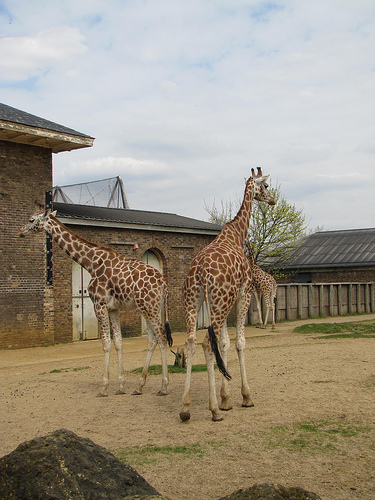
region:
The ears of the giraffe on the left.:
[46, 211, 57, 215]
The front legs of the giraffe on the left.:
[95, 311, 123, 395]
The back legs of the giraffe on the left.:
[132, 301, 169, 394]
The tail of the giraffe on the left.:
[161, 284, 172, 347]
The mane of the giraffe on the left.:
[48, 216, 124, 258]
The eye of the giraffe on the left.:
[27, 218, 37, 223]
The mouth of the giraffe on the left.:
[16, 231, 25, 236]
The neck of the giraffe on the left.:
[50, 218, 96, 268]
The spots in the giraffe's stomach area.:
[98, 256, 137, 307]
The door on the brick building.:
[75, 257, 101, 334]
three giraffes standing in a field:
[26, 172, 298, 425]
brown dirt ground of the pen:
[32, 385, 105, 430]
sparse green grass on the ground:
[259, 395, 369, 468]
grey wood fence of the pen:
[281, 283, 345, 319]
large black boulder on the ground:
[6, 418, 148, 498]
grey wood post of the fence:
[296, 286, 303, 316]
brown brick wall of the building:
[1, 244, 36, 321]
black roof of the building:
[97, 207, 154, 222]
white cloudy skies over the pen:
[118, 105, 228, 177]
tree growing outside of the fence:
[219, 194, 300, 285]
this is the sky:
[140, 11, 230, 68]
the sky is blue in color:
[21, 78, 37, 87]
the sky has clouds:
[149, 79, 236, 146]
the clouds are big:
[162, 92, 196, 121]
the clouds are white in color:
[154, 57, 212, 107]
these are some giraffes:
[16, 158, 295, 395]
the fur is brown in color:
[211, 259, 236, 293]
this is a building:
[14, 111, 369, 324]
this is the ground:
[194, 446, 224, 474]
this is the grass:
[149, 444, 183, 452]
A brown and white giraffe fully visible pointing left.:
[16, 204, 175, 395]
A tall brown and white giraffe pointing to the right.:
[177, 164, 276, 420]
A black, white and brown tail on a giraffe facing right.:
[201, 277, 233, 381]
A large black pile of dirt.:
[0, 427, 166, 498]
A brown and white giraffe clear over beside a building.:
[242, 237, 277, 329]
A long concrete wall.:
[250, 282, 374, 323]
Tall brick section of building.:
[0, 141, 51, 348]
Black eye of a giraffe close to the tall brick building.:
[27, 217, 36, 223]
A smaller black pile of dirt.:
[216, 481, 322, 499]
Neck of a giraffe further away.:
[245, 238, 255, 265]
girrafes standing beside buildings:
[61, 226, 307, 434]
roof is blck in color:
[77, 194, 185, 220]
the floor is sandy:
[275, 361, 347, 422]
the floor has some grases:
[269, 412, 367, 480]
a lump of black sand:
[24, 418, 132, 489]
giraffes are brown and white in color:
[47, 215, 277, 376]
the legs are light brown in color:
[222, 329, 252, 394]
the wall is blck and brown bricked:
[10, 260, 45, 329]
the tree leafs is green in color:
[262, 212, 286, 256]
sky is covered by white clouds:
[200, 64, 301, 128]